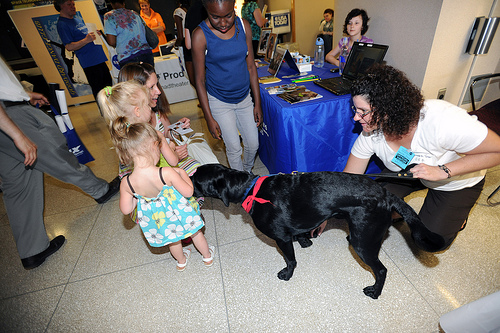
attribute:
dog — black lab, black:
[189, 162, 449, 303]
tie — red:
[239, 170, 273, 217]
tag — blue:
[390, 145, 416, 172]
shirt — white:
[344, 99, 491, 191]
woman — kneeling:
[335, 67, 499, 254]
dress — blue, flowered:
[126, 165, 209, 250]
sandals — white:
[172, 244, 217, 271]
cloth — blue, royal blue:
[251, 58, 387, 178]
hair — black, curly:
[349, 63, 424, 144]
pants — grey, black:
[0, 105, 109, 263]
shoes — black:
[19, 170, 124, 270]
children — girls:
[96, 79, 216, 270]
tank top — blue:
[196, 15, 253, 104]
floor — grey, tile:
[0, 100, 499, 332]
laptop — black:
[313, 41, 387, 99]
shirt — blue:
[53, 13, 110, 72]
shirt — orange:
[140, 8, 174, 55]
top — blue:
[313, 35, 325, 47]